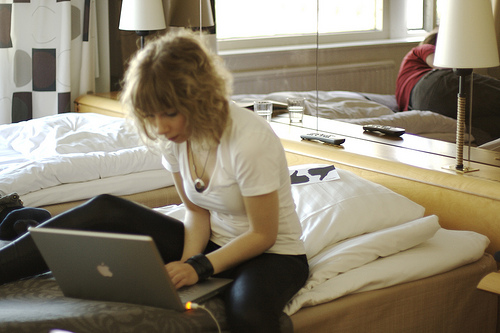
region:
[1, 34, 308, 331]
a woman sitting on a bed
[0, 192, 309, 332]
woman sitting on a bed with her leg propped on the mattress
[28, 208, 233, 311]
a woman typing at a laptop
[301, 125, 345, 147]
a remote on a wooden ledge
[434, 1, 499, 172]
a lamp with white lampshade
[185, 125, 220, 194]
a woman wearing a pendant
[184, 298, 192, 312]
orange light on a laptop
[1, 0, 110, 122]
white and brown drapes on a window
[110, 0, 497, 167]
a mirror behind a bed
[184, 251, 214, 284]
woman wearing two black bracelets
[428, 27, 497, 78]
white shade on lamp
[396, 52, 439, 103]
red t shirt on man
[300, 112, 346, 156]
black remote on ledge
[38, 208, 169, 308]
apple macbook air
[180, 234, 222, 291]
black leather on wrist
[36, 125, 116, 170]
white bed cover with made bed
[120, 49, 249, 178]
woman looking down at computer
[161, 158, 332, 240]
white v neck on woman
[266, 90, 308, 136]
clear glass of water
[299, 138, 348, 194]
brochure with black and white hands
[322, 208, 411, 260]
white pillow on bed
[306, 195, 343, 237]
white pillow has stripes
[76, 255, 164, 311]
apple on laptop back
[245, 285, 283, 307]
woman in black pants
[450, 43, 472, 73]
beige lampshade on lamp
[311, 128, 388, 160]
gray remote on bed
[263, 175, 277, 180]
woman wearing white shirt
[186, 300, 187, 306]
orange light on laptop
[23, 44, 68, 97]
curtain is black and white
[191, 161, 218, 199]
woman wearing necklace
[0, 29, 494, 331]
woman using laptop computer on bed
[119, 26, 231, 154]
woman has messy dark blonde hair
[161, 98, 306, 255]
woman wearing plain white t-shirt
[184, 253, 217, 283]
woman wearing black band on wrist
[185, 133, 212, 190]
woman wearing silver chain necklace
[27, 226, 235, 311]
silver laptop computer is Mac brand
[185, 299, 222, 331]
power cord connection is glowing yellow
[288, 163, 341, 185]
white paper with picture of black hands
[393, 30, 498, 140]
reflection of man in bedroom mirror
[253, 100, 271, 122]
partially full plastic glass of water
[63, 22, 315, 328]
Girl on a lap top.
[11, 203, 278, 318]
Lap top on the bed.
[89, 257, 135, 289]
Apple on the lap top.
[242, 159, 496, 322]
Pillow behind the girl.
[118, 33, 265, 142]
Curly hair on the girl.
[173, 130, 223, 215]
Necklace on the girl.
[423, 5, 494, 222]
Lamp on the table.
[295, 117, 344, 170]
Remote on the ledge.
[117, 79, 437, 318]
White shirt on the girl.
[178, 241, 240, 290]
Black wristband on the girl.